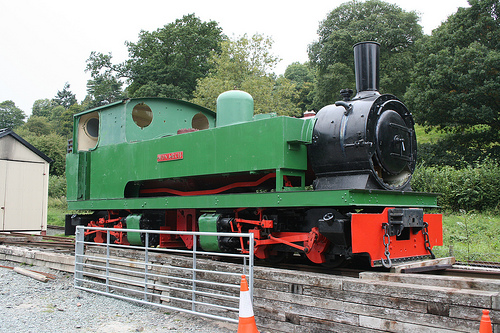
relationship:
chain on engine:
[365, 223, 402, 276] [63, 40, 458, 274]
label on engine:
[153, 139, 200, 169] [63, 40, 458, 274]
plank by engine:
[1, 245, 499, 331] [63, 40, 458, 274]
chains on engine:
[375, 212, 454, 267] [63, 40, 458, 274]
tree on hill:
[420, 26, 481, 131] [386, 56, 496, 218]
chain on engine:
[365, 223, 402, 271] [63, 40, 458, 274]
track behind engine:
[41, 235, 96, 255] [63, 40, 458, 274]